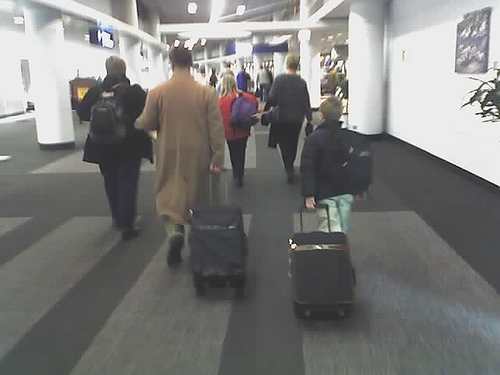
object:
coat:
[134, 75, 224, 225]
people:
[300, 96, 370, 233]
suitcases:
[288, 230, 357, 320]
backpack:
[324, 129, 374, 194]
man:
[133, 47, 225, 266]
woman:
[219, 70, 261, 188]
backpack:
[230, 93, 259, 128]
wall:
[383, 1, 498, 190]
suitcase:
[188, 205, 244, 296]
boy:
[300, 97, 368, 232]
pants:
[317, 193, 354, 233]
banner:
[253, 43, 288, 53]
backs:
[157, 82, 208, 148]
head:
[169, 48, 192, 68]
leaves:
[459, 67, 499, 124]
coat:
[75, 79, 153, 164]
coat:
[219, 90, 258, 140]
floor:
[0, 109, 497, 374]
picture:
[454, 7, 489, 73]